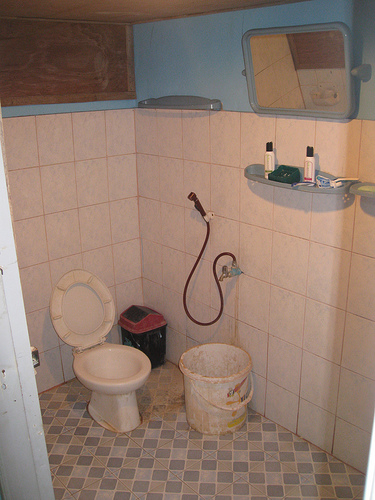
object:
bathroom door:
[0, 150, 55, 498]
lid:
[49, 265, 115, 353]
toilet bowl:
[48, 266, 151, 432]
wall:
[94, 96, 135, 208]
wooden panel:
[0, 0, 139, 108]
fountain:
[183, 190, 237, 325]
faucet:
[218, 262, 242, 281]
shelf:
[243, 163, 351, 196]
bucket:
[177, 341, 254, 436]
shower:
[183, 190, 242, 325]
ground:
[38, 360, 367, 498]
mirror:
[248, 29, 347, 114]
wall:
[132, 1, 373, 117]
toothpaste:
[315, 175, 342, 190]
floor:
[205, 427, 363, 499]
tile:
[175, 454, 240, 499]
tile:
[44, 429, 86, 469]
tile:
[241, 419, 297, 458]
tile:
[87, 431, 145, 473]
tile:
[125, 415, 180, 454]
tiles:
[67, 416, 117, 454]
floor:
[135, 435, 203, 499]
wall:
[0, 111, 146, 392]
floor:
[40, 384, 79, 448]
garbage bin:
[117, 304, 168, 369]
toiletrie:
[303, 145, 315, 187]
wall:
[264, 229, 321, 335]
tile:
[310, 455, 367, 498]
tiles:
[304, 240, 351, 310]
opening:
[0, 20, 125, 101]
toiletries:
[263, 140, 275, 179]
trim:
[339, 26, 361, 120]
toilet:
[0, 22, 374, 499]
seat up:
[48, 266, 116, 354]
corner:
[123, 108, 154, 304]